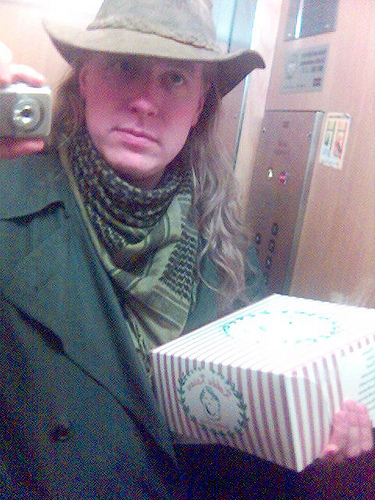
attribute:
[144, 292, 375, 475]
box — white, pink, red, green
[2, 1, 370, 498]
man — caucasian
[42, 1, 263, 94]
hat — grey, beige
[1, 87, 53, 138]
camera — silver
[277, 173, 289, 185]
button — red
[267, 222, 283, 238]
button — black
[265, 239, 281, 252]
button — black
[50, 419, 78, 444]
button — round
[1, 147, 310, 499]
jacket — green, gray, black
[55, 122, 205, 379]
scarf — black, gray, green, blue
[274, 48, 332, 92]
plaque — silver, gray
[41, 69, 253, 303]
hair — long, blond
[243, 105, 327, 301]
panel — silver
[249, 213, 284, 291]
buttons — black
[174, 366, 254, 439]
emblem — white